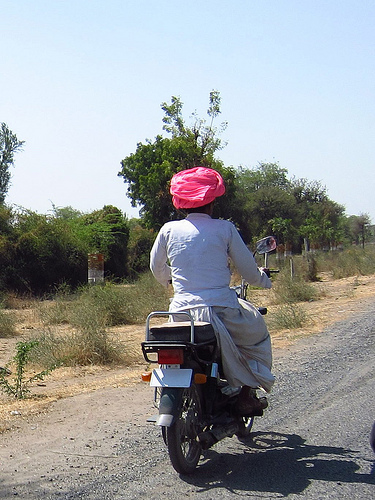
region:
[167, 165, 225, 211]
turban is worn on head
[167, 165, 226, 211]
turban is worn by human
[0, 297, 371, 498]
road is covered in gravel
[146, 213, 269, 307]
jacket is worn by human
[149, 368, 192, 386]
license plate is attached to scooter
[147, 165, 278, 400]
human rides scooter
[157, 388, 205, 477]
wheel is attached to schooter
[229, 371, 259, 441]
wheel is attached to scooter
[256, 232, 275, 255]
rearview mirror allows driver to look behind them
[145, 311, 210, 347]
back seat of scooter is empty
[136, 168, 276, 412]
man riding motorcycle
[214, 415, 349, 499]
shadow of rider and bike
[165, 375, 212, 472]
black wheel of bike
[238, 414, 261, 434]
black wheel of bike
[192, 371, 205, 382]
orange light of bike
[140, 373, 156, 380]
orange light of bike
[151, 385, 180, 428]
black mud guard on bike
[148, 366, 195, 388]
white plate on back of bike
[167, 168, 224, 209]
pink hat on rider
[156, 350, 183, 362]
red light on back of bike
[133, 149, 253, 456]
woman riding bike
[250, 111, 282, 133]
white clouds in blue sky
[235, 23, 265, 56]
white clouds in blue sky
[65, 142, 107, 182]
white clouds in blue sky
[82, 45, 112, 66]
white clouds in blue sky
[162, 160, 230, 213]
pink hat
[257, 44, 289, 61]
white clouds in blue sky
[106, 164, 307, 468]
person riding a motorbike during daytime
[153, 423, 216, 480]
rear wheel on roadway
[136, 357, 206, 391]
tag area on bike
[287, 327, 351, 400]
patch of gravel roadway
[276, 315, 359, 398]
patch of gray gravel roadway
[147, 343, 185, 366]
red tail light area in view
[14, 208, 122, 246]
some green trees in view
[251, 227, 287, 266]
rear view mirror on bike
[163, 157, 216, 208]
red hat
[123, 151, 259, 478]
woman on bike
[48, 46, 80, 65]
white clouds in blue sky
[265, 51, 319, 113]
white clouds in blue sky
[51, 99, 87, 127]
white clouds in blue sky